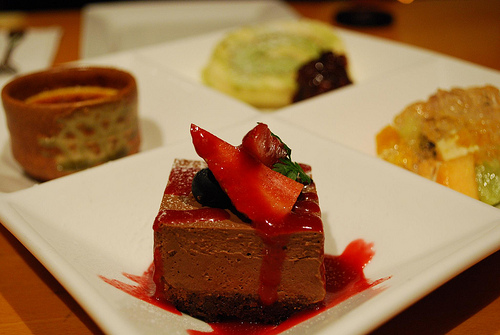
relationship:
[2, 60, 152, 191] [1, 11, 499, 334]
bowl on plate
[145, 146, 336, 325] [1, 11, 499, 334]
pastry on plate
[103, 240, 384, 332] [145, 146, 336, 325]
sauce bottom of pastry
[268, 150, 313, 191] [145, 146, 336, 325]
leaf on pastry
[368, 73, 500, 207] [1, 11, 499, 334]
pastry on plate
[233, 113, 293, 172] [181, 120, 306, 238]
strawberry on strawberry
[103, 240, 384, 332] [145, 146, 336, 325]
sauce on pastry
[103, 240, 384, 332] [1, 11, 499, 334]
sauce on plate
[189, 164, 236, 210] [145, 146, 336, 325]
blueberry on pastry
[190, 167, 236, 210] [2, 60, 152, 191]
blueberry in bowl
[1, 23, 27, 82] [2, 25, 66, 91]
fork on napkin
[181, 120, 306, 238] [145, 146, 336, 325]
strawberry on pastry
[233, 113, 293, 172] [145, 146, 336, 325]
strawberry on pastry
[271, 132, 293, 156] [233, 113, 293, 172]
stem of strawberry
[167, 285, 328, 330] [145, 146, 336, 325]
crust of pastry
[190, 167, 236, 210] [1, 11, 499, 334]
blueberry on plate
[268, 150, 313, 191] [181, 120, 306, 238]
leaf on strawberry